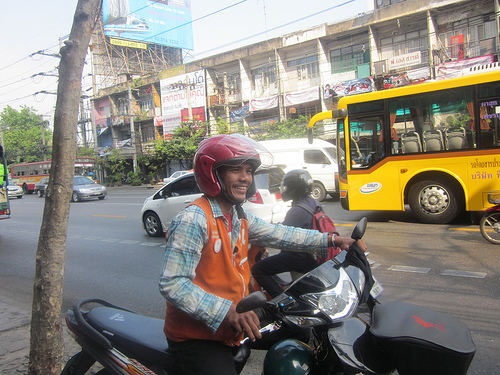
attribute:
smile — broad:
[230, 181, 252, 193]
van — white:
[249, 132, 351, 197]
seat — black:
[88, 306, 170, 361]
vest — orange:
[162, 189, 254, 349]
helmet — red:
[192, 135, 260, 203]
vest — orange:
[164, 195, 258, 345]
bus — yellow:
[304, 67, 498, 225]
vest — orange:
[176, 200, 260, 335]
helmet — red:
[197, 130, 280, 204]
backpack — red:
[297, 198, 371, 314]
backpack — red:
[299, 200, 347, 255]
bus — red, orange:
[301, 68, 498, 245]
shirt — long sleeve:
[143, 190, 253, 342]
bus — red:
[9, 152, 52, 197]